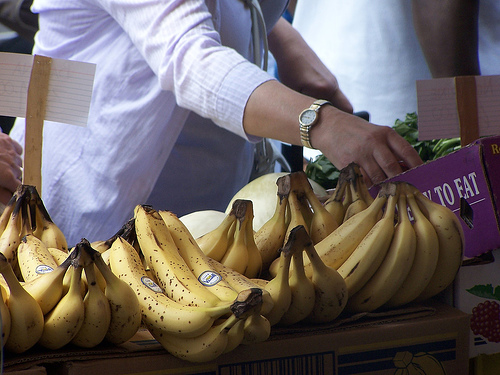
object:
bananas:
[350, 195, 417, 313]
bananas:
[324, 170, 349, 225]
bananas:
[39, 266, 85, 351]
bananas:
[29, 197, 68, 254]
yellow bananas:
[390, 200, 437, 308]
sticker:
[141, 276, 164, 294]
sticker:
[197, 270, 222, 288]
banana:
[131, 203, 230, 313]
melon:
[225, 173, 325, 233]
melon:
[176, 209, 232, 239]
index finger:
[387, 130, 421, 169]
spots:
[171, 283, 179, 289]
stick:
[22, 53, 51, 191]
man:
[7, 0, 426, 247]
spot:
[147, 302, 153, 314]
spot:
[175, 323, 182, 335]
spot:
[167, 276, 173, 284]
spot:
[152, 248, 160, 254]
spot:
[154, 258, 159, 263]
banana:
[103, 235, 231, 339]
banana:
[251, 241, 290, 325]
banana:
[304, 246, 350, 323]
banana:
[418, 195, 468, 305]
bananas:
[4, 254, 44, 355]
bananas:
[17, 233, 75, 294]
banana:
[203, 256, 275, 316]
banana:
[100, 263, 144, 349]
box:
[367, 134, 500, 259]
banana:
[161, 211, 240, 302]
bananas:
[269, 197, 388, 281]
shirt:
[9, 0, 288, 251]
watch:
[298, 99, 331, 149]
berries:
[466, 286, 500, 344]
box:
[441, 248, 499, 352]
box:
[0, 300, 472, 374]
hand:
[314, 109, 423, 183]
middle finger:
[373, 143, 403, 180]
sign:
[0, 52, 97, 128]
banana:
[148, 315, 238, 363]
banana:
[193, 217, 235, 263]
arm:
[102, 1, 298, 129]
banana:
[290, 253, 316, 327]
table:
[15, 315, 454, 375]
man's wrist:
[294, 97, 340, 149]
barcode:
[219, 351, 338, 373]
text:
[421, 171, 480, 208]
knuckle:
[344, 141, 370, 165]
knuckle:
[360, 125, 384, 146]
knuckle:
[377, 124, 396, 141]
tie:
[248, 0, 273, 71]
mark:
[147, 297, 157, 315]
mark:
[153, 305, 164, 329]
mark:
[183, 313, 201, 331]